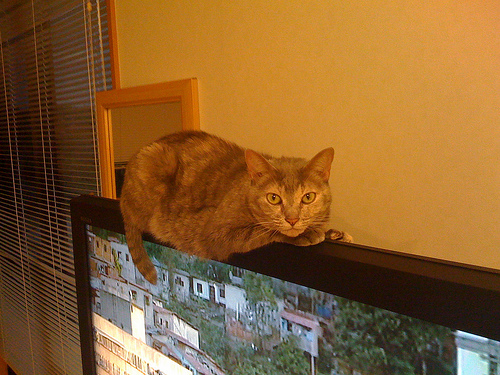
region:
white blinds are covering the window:
[1, 4, 116, 372]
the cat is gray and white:
[122, 125, 354, 287]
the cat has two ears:
[241, 142, 338, 187]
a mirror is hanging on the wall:
[95, 74, 202, 206]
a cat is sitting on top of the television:
[65, 124, 495, 372]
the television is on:
[73, 197, 498, 372]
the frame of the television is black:
[67, 192, 497, 369]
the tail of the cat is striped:
[119, 199, 164, 291]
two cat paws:
[295, 220, 360, 250]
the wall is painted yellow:
[107, 0, 498, 270]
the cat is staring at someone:
[148, 143, 367, 235]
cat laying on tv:
[135, 140, 288, 371]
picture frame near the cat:
[110, 85, 211, 156]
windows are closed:
[50, 51, 110, 132]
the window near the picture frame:
[48, 52, 193, 147]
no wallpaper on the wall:
[340, 72, 420, 145]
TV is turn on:
[142, 270, 304, 332]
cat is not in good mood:
[176, 160, 331, 220]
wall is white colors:
[370, 52, 446, 132]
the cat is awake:
[310, 148, 337, 172]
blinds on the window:
[2, 5, 74, 355]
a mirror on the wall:
[96, 94, 190, 141]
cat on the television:
[138, 152, 307, 240]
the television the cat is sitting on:
[70, 247, 498, 370]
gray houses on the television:
[95, 242, 190, 344]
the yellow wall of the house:
[215, 25, 496, 159]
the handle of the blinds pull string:
[82, 2, 96, 19]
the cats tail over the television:
[107, 198, 162, 290]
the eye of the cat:
[299, 193, 315, 203]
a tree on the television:
[328, 304, 430, 373]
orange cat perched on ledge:
[116, 128, 368, 283]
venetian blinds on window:
[0, 129, 101, 192]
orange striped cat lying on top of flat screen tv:
[72, 124, 415, 361]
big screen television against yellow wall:
[69, 189, 481, 374]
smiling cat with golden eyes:
[232, 143, 347, 262]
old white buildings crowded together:
[85, 260, 210, 370]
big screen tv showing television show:
[70, 195, 470, 370]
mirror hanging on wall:
[90, 85, 200, 200]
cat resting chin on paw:
[235, 145, 356, 256]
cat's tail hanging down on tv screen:
[112, 200, 169, 306]